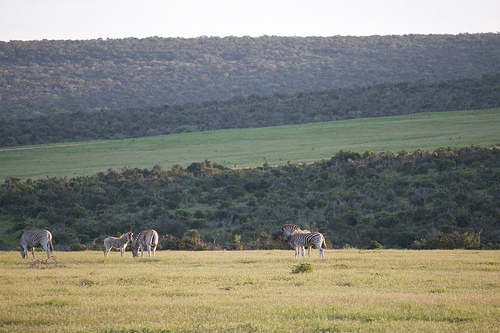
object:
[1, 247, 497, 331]
grass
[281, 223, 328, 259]
zebra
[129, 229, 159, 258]
zebra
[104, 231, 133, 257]
zebra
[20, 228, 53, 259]
zebra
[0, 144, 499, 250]
trees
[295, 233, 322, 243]
stripes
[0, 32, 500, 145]
hill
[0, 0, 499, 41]
sky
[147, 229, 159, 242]
butt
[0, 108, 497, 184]
land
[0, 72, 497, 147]
trees